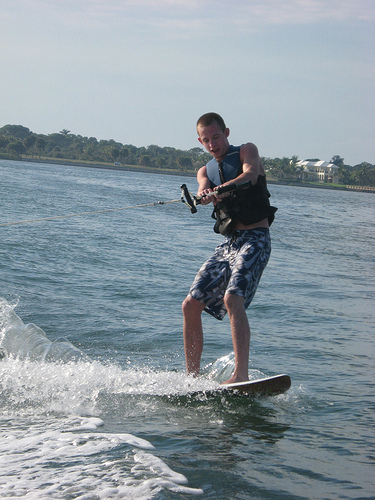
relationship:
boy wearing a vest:
[180, 111, 277, 389] [201, 144, 280, 238]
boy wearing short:
[180, 111, 277, 389] [188, 224, 271, 320]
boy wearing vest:
[180, 111, 277, 389] [204, 145, 276, 232]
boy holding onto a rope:
[180, 111, 277, 389] [0, 190, 215, 226]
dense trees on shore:
[13, 117, 124, 164] [0, 147, 374, 192]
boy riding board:
[180, 111, 277, 389] [95, 370, 290, 397]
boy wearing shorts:
[180, 111, 277, 389] [186, 231, 304, 339]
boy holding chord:
[180, 111, 277, 389] [141, 199, 166, 211]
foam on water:
[0, 287, 334, 499] [0, 157, 372, 498]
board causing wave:
[130, 367, 292, 405] [14, 356, 143, 423]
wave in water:
[14, 356, 143, 423] [63, 244, 157, 295]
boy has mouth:
[180, 111, 277, 389] [208, 147, 221, 155]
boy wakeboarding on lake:
[179, 108, 277, 389] [1, 160, 373, 498]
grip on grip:
[181, 178, 247, 201] [181, 179, 254, 215]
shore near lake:
[0, 147, 374, 192] [1, 160, 373, 498]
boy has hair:
[180, 111, 277, 389] [196, 112, 226, 137]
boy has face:
[180, 111, 277, 389] [196, 120, 225, 158]